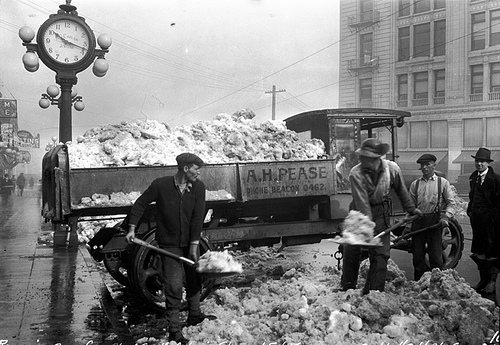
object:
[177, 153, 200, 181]
head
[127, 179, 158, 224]
arm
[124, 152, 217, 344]
man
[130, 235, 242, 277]
shovel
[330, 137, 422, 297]
man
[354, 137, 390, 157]
hat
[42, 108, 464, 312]
truck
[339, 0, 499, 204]
building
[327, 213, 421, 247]
shovel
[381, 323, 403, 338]
rock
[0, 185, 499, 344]
ground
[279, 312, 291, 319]
rock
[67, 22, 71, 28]
number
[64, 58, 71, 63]
number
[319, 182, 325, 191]
number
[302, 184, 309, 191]
number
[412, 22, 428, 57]
window